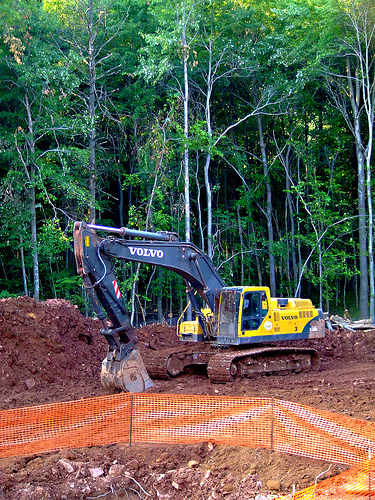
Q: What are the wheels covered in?
A: Dirt.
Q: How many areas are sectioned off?
A: 1.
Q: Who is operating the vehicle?
A: No one.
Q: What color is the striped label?
A: Red and white.